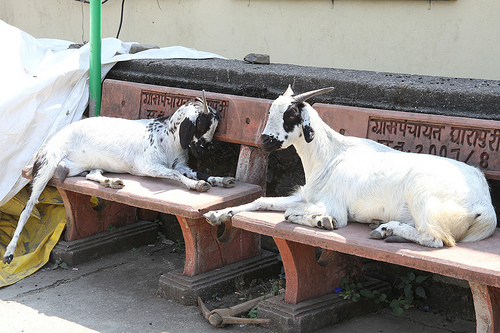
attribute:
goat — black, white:
[242, 88, 487, 283]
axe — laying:
[185, 287, 296, 330]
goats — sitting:
[86, 84, 446, 237]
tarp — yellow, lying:
[3, 144, 75, 289]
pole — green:
[78, 30, 118, 112]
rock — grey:
[208, 46, 284, 84]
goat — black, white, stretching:
[46, 99, 236, 249]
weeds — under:
[335, 264, 429, 330]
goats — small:
[236, 92, 456, 274]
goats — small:
[234, 79, 474, 272]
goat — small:
[250, 106, 413, 232]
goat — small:
[293, 88, 483, 280]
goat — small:
[231, 101, 483, 294]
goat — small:
[233, 92, 478, 272]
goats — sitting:
[46, 93, 411, 250]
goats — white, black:
[44, 60, 464, 234]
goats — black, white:
[239, 103, 469, 258]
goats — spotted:
[0, 90, 267, 230]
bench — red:
[139, 68, 412, 319]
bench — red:
[18, 71, 499, 329]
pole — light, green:
[86, 0, 107, 119]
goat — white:
[201, 80, 498, 252]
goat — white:
[0, 89, 237, 272]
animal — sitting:
[196, 81, 499, 251]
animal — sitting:
[0, 91, 234, 271]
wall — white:
[3, 0, 497, 82]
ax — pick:
[183, 288, 271, 330]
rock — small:
[237, 47, 274, 67]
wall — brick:
[94, 43, 499, 120]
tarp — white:
[0, 10, 235, 217]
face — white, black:
[159, 99, 226, 166]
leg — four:
[199, 191, 287, 230]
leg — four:
[288, 200, 342, 235]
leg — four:
[367, 217, 445, 253]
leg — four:
[364, 219, 391, 245]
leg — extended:
[0, 152, 64, 263]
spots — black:
[174, 117, 195, 150]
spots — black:
[192, 107, 212, 137]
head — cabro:
[159, 90, 228, 160]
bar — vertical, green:
[79, 3, 112, 121]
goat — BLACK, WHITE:
[253, 95, 477, 265]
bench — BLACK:
[153, 190, 205, 253]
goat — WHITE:
[32, 103, 221, 190]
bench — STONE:
[371, 110, 461, 142]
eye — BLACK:
[283, 102, 309, 132]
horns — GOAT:
[284, 81, 328, 105]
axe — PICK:
[183, 279, 272, 331]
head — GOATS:
[260, 72, 328, 162]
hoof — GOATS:
[202, 209, 224, 227]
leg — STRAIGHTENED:
[197, 186, 280, 234]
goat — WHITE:
[241, 99, 481, 249]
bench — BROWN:
[335, 234, 372, 250]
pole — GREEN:
[85, 24, 104, 106]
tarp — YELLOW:
[33, 215, 56, 245]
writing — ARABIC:
[373, 119, 444, 151]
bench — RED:
[60, 95, 497, 284]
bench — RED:
[79, 75, 496, 301]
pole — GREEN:
[77, 5, 102, 179]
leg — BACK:
[10, 161, 42, 271]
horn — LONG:
[289, 74, 337, 109]